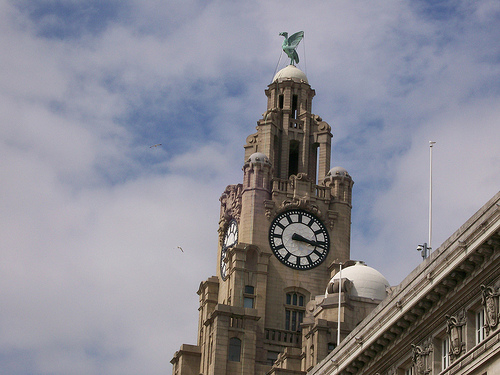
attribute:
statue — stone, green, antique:
[280, 30, 305, 68]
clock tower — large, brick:
[171, 82, 352, 373]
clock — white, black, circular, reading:
[270, 209, 331, 270]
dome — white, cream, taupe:
[274, 66, 310, 84]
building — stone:
[303, 262, 400, 369]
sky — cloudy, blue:
[2, 4, 498, 374]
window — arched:
[285, 289, 307, 331]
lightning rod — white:
[428, 140, 438, 266]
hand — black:
[293, 233, 324, 250]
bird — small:
[175, 246, 185, 252]